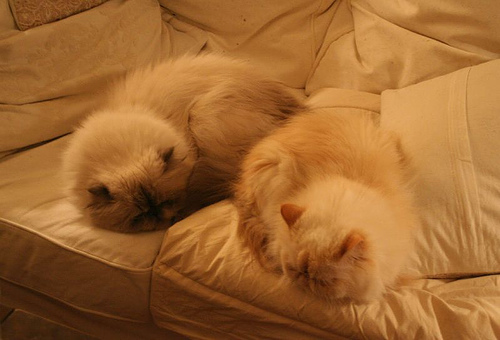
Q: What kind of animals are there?
A: Cats.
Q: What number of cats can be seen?
A: Two.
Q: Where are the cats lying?
A: On a couch.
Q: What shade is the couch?
A: White.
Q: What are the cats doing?
A: Sleeping.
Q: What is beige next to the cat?
A: Couch cushion.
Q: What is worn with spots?
A: The cushion.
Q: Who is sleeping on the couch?
A: Two fluffy cats.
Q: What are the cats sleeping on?
A: A white couch.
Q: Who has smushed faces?
A: The cats.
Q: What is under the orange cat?
A: A pillow.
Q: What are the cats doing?
A: Sleeping.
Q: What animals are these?
A: Cats.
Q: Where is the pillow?
A: Under the cat.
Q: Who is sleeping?
A: The cats.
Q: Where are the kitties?
A: On the couch.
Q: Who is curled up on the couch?
A: Cats.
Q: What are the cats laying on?
A: Couch.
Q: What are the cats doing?
A: Sleeping.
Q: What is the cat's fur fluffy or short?
A: Fluffy.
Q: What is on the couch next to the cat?
A: Pillow.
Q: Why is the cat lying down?
A: Sleeping.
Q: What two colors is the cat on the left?
A: Brown and white.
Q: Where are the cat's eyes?
A: Covered.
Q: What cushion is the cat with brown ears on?
A: Left.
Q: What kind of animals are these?
A: Cats.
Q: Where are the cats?
A: Couch.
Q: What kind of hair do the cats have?
A: Long hair.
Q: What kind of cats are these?
A: Long haired white cats.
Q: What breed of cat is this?
A: Persian.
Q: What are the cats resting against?
A: Cushions.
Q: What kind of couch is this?
A: White couch.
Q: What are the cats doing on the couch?
A: Sleeping.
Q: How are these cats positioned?
A: Next to each other.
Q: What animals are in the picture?
A: Cats.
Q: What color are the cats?
A: White.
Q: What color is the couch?
A: White.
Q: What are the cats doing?
A: Sleeping.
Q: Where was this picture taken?
A: A living room.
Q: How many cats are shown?
A: Two.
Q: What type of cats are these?
A: Long haired.